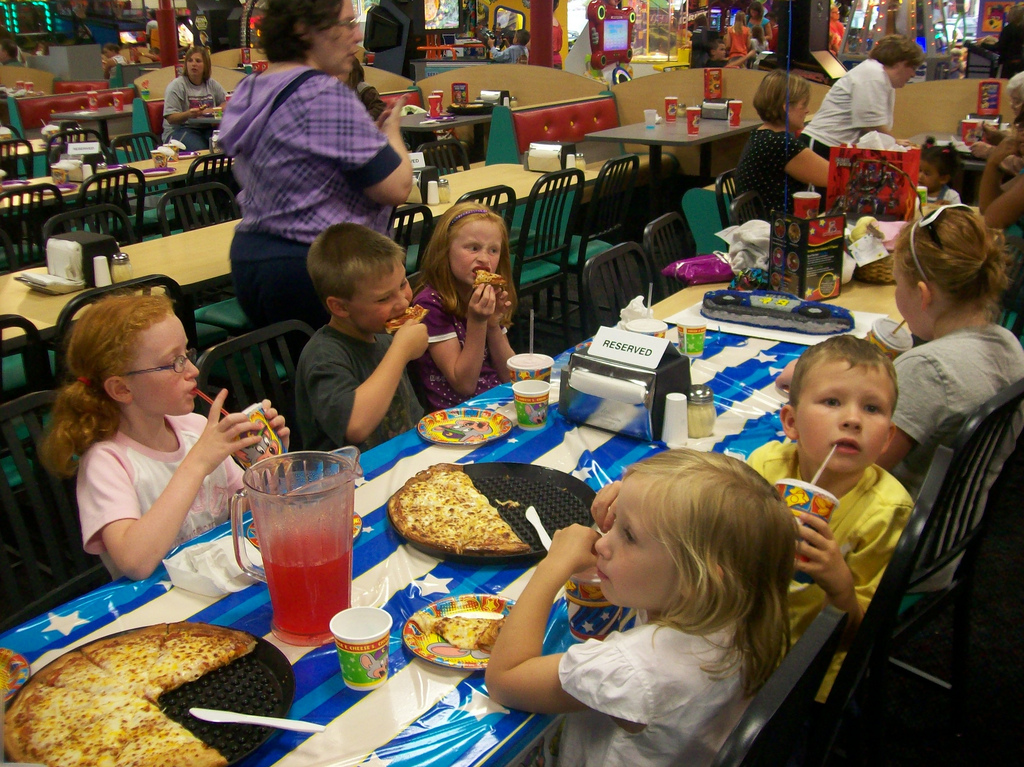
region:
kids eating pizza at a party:
[39, 280, 290, 578]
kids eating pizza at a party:
[288, 220, 429, 440]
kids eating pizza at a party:
[406, 198, 521, 407]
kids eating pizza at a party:
[482, 441, 795, 761]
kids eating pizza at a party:
[980, 72, 1022, 235]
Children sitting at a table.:
[33, 171, 1021, 734]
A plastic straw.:
[807, 443, 846, 483]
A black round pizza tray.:
[385, 453, 613, 571]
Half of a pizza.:
[384, 453, 610, 567]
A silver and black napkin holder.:
[572, 339, 681, 434]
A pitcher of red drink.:
[232, 458, 372, 645]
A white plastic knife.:
[188, 695, 338, 757]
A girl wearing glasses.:
[31, 292, 326, 591]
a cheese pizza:
[401, 487, 485, 542]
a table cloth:
[348, 710, 440, 755]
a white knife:
[187, 699, 308, 737]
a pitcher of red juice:
[271, 516, 349, 602]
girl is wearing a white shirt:
[598, 650, 693, 711]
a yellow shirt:
[851, 500, 894, 540]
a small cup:
[333, 611, 400, 692]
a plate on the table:
[418, 394, 513, 453]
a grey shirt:
[932, 343, 999, 398]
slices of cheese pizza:
[0, 611, 311, 764]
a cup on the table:
[324, 586, 402, 707]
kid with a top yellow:
[752, 311, 930, 606]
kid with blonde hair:
[403, 186, 550, 380]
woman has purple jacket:
[212, 6, 435, 235]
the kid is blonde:
[853, 179, 1022, 414]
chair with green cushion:
[515, 156, 585, 346]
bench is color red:
[506, 85, 693, 172]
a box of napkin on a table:
[8, 213, 129, 309]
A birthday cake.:
[675, 281, 866, 364]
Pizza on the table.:
[53, 458, 594, 757]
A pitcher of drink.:
[210, 456, 397, 640]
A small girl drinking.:
[22, 278, 294, 598]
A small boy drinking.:
[754, 336, 919, 621]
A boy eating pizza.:
[290, 203, 452, 447]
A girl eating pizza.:
[414, 184, 533, 410]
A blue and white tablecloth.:
[12, 325, 869, 755]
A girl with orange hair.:
[0, 248, 288, 580]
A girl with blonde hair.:
[488, 449, 809, 762]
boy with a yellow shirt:
[714, 325, 924, 718]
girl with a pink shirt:
[32, 290, 282, 591]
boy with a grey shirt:
[284, 218, 444, 452]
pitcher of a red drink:
[215, 448, 368, 654]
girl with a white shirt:
[482, 443, 781, 764]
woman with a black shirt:
[717, 70, 850, 236]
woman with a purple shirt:
[209, 0, 428, 343]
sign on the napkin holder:
[588, 318, 671, 373]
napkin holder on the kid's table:
[562, 339, 696, 453]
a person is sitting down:
[27, 288, 290, 527]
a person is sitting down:
[305, 223, 442, 438]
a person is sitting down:
[419, 190, 521, 390]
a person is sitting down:
[706, 74, 836, 233]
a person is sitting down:
[481, 438, 799, 764]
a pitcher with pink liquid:
[228, 442, 378, 649]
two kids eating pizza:
[302, 203, 531, 456]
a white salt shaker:
[659, 385, 695, 449]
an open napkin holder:
[15, 227, 115, 301]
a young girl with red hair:
[31, 285, 202, 488]